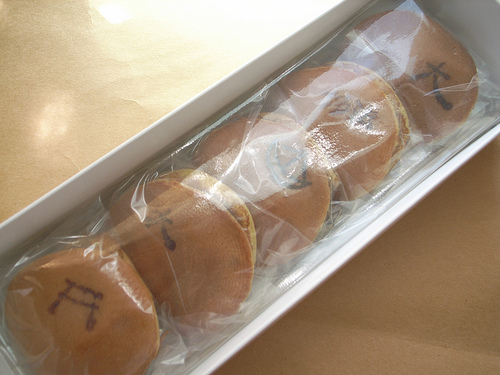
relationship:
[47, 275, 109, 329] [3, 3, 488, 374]
chinese letter on pancake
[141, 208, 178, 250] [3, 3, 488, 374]
chinese letter on pancake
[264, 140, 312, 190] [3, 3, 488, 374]
chinese letter on pancake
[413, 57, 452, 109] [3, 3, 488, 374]
chinese letter on pancake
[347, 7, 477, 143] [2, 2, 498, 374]
cale in cardboard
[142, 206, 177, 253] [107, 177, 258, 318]
chinese letter on pancake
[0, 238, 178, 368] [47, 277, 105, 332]
cake with chinese letter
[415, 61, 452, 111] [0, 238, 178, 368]
chinese letter lettering on cake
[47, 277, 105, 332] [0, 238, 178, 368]
chinese letter on cake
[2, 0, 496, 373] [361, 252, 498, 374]
tray over surface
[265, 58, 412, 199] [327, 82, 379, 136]
pancake has chinese letter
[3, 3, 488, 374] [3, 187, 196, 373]
pancake in bag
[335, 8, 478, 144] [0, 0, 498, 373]
pancake in bag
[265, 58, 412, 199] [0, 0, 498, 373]
pancake in bag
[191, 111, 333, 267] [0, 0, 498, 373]
pancake in bag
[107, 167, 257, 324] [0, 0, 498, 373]
pancake in bag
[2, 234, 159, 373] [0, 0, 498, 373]
pancake in bag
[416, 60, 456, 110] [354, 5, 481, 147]
sign on cake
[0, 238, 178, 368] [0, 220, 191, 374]
cake wrapped in plastic wrapper